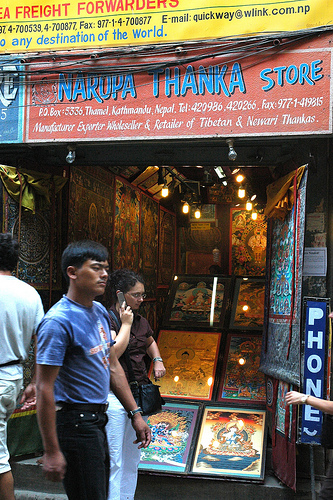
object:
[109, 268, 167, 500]
woman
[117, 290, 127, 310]
phone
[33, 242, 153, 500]
man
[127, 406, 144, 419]
watch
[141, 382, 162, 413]
bag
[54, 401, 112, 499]
pants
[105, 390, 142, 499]
pants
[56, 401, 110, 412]
belt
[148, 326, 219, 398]
painting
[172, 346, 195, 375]
buddha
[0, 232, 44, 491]
man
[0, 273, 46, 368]
shirt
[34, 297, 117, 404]
shirt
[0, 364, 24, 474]
shorts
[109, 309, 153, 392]
shirt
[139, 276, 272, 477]
art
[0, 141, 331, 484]
store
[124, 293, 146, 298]
glasses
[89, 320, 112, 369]
image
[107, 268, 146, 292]
hair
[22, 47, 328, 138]
sign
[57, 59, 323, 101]
lettering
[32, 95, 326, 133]
letters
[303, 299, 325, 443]
sign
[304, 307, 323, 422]
phone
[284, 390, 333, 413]
forearm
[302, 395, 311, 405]
watch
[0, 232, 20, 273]
hair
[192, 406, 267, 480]
painting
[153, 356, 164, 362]
watch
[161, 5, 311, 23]
email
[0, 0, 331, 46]
sign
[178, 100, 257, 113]
number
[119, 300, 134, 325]
hand